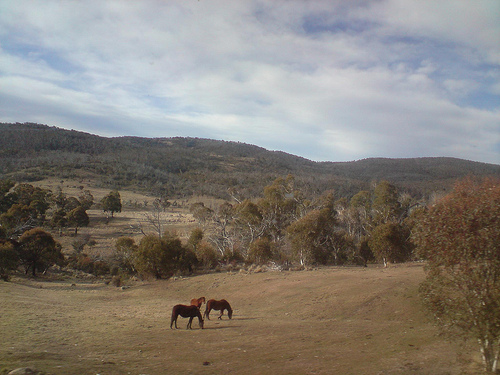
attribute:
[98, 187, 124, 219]
tree — on a hillside, green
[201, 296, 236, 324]
horse — grazing in field, big, grazing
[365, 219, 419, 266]
tree — on right side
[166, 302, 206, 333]
horse — dark, brown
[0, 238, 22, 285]
tree — on the left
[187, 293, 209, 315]
horse — light brown, brown, facing camera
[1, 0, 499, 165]
sky — mostly cloudy, blue color, cloudy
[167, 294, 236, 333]
horses — wild, grazing together, looking for grass, in wide open field, grazing in  pasture, feeding, standing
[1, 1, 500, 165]
clouds — white in color, in the sky, white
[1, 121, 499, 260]
mountains — hilly, in background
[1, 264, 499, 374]
ground — covered in soil, brown, dying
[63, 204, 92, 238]
tree — green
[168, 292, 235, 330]
three horses — standing together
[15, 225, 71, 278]
tree — green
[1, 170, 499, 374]
field — open, grassy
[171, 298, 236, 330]
two stallions — in the field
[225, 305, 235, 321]
horse's head — downward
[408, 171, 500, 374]
tree — tall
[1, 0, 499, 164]
high altitude clouds — in the sky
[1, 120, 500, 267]
hills — in the background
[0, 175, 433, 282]
trees — in the background